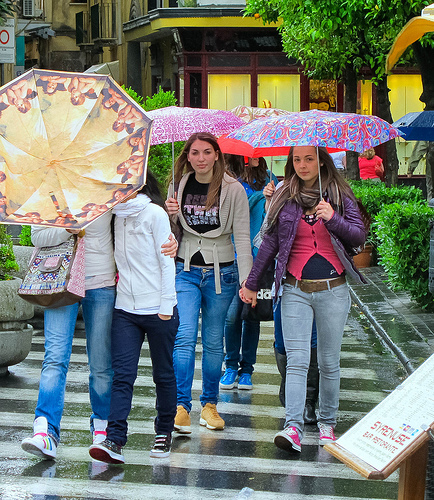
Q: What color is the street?
A: Black and white.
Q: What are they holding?
A: Umbrellas.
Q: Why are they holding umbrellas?
A: To protect from rain.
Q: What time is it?
A: Daytime.